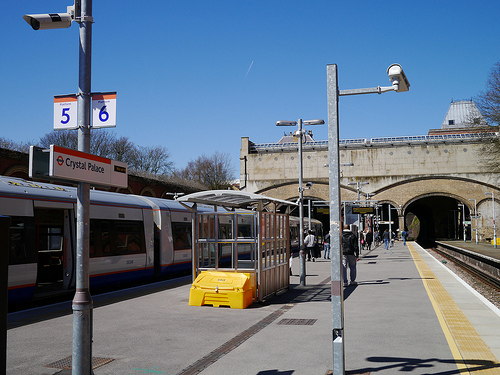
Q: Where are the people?
A: On the train platform.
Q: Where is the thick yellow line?
A: Near the edge of the platform.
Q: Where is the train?
A: On the tracks to the left.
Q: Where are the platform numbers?
A: On the pole.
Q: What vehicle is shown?
A: A train.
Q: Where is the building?
A: Over the track.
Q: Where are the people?
A: By the train.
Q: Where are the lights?
A: On the poles.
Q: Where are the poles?
A: By the train.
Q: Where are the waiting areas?
A: By the train.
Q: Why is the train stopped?
A: To let people on and off.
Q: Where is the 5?
A: On the sign.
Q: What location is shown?
A: A train station.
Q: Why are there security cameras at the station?
A: To protect people.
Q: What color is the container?
A: Yellow.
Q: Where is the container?
A: Train stop.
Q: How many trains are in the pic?
A: 1.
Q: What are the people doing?
A: Walking.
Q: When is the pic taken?
A: Daytime.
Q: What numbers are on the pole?
A: 5 & 6.